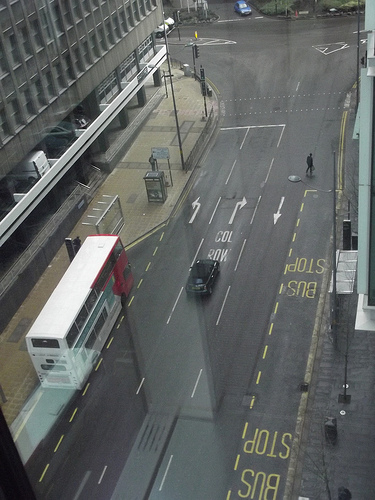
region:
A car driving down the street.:
[177, 253, 224, 299]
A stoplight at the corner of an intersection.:
[183, 41, 200, 83]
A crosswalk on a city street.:
[210, 89, 357, 115]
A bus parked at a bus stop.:
[21, 221, 134, 401]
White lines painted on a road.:
[171, 115, 296, 259]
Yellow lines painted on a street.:
[282, 185, 321, 254]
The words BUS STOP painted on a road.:
[276, 254, 327, 303]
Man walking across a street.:
[297, 149, 317, 180]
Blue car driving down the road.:
[227, 1, 258, 18]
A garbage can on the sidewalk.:
[317, 412, 346, 454]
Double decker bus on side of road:
[21, 232, 140, 390]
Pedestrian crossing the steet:
[303, 150, 317, 177]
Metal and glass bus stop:
[80, 192, 127, 235]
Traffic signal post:
[187, 41, 201, 76]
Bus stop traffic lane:
[223, 185, 342, 498]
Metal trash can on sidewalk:
[320, 415, 340, 444]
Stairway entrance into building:
[74, 159, 110, 202]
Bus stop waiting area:
[329, 247, 358, 327]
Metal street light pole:
[156, 8, 196, 171]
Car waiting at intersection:
[227, 0, 256, 17]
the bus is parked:
[30, 248, 141, 395]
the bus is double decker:
[24, 225, 141, 404]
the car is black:
[164, 250, 229, 315]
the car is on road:
[180, 249, 249, 310]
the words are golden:
[233, 415, 287, 497]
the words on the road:
[240, 423, 288, 495]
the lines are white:
[141, 429, 210, 498]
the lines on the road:
[144, 425, 197, 498]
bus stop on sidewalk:
[84, 188, 142, 252]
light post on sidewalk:
[150, 40, 195, 173]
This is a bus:
[15, 220, 156, 406]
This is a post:
[153, 3, 193, 177]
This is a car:
[178, 247, 224, 304]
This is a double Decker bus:
[17, 209, 148, 411]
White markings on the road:
[252, 112, 291, 183]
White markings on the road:
[225, 224, 255, 288]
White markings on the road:
[180, 356, 234, 429]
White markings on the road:
[133, 362, 161, 438]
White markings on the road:
[118, 333, 166, 411]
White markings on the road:
[179, 227, 222, 268]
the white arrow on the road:
[187, 196, 200, 224]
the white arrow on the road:
[228, 194, 247, 224]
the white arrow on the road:
[273, 196, 284, 224]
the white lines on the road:
[73, 15, 361, 497]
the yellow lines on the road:
[38, 75, 349, 497]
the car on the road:
[185, 260, 220, 296]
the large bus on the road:
[24, 234, 133, 391]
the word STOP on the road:
[243, 427, 291, 458]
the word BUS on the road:
[287, 279, 317, 299]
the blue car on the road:
[234, 1, 252, 16]